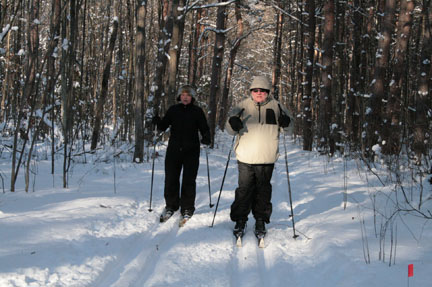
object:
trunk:
[132, 0, 146, 163]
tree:
[317, 12, 338, 161]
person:
[224, 73, 292, 238]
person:
[144, 81, 212, 224]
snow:
[2, 174, 430, 285]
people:
[151, 86, 212, 228]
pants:
[158, 145, 206, 212]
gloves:
[227, 111, 247, 133]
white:
[1, 198, 143, 286]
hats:
[175, 79, 200, 100]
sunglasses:
[251, 87, 272, 95]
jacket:
[151, 104, 210, 149]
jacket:
[224, 93, 293, 165]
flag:
[404, 261, 416, 286]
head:
[176, 82, 200, 108]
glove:
[198, 134, 216, 147]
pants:
[229, 160, 274, 224]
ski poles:
[210, 132, 238, 226]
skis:
[219, 234, 272, 250]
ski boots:
[234, 210, 272, 248]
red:
[406, 263, 414, 276]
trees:
[132, 1, 145, 164]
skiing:
[208, 76, 313, 248]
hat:
[246, 72, 277, 91]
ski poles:
[281, 125, 308, 242]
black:
[152, 103, 212, 209]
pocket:
[264, 106, 279, 126]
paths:
[92, 235, 306, 286]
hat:
[172, 80, 201, 103]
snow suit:
[156, 103, 216, 216]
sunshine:
[197, 9, 310, 69]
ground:
[0, 245, 431, 285]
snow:
[33, 201, 94, 262]